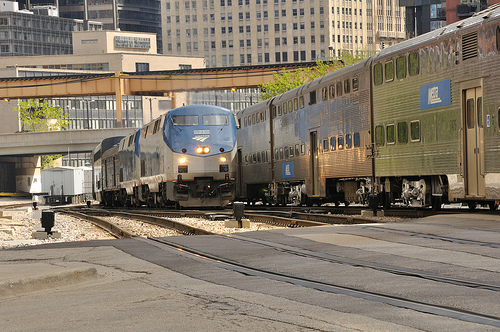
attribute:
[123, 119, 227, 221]
train — large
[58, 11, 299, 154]
buildings — large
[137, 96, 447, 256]
trains — large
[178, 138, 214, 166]
lights — bright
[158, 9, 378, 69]
building — large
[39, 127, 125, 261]
buildings — white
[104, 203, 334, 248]
tracks — silver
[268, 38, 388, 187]
train — silver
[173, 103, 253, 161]
windshield — clear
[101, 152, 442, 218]
wheels — metallic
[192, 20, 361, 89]
apartment — tan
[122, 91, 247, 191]
train — silver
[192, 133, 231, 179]
lights — bright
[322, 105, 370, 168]
screen — small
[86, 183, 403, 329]
tracks — silver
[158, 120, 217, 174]
headlights — light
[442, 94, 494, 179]
door — silver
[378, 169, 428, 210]
wheels — silver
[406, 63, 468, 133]
logo — grey, blue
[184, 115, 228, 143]
windows — thin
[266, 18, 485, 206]
trains — double decker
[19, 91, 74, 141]
leaves — green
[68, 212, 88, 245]
gravel — sand colored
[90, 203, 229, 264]
tracks — train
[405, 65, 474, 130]
sign — blue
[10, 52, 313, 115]
tracks — overhead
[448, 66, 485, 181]
doors — side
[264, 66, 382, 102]
leaves — green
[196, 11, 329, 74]
building — tall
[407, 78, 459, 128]
sign — blue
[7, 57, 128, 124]
wires — electrical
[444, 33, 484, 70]
vent — side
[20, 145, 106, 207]
building — white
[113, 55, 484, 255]
trains — moving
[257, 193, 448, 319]
tracks — blue, silver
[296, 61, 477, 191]
cars — train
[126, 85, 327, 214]
train — blue, upper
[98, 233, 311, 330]
road — asphalt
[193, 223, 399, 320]
tracks — train, railroad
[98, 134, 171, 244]
train — blue